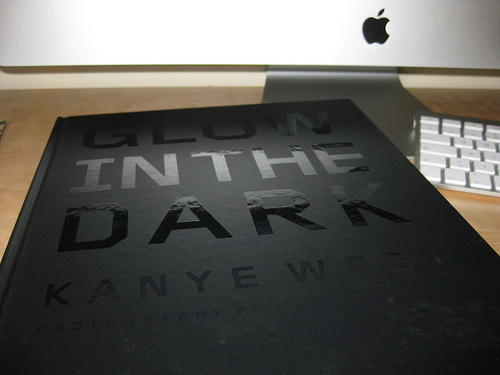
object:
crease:
[0, 116, 66, 300]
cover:
[0, 98, 500, 374]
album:
[0, 96, 500, 374]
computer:
[0, 0, 500, 157]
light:
[121, 153, 136, 173]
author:
[43, 247, 448, 308]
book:
[0, 97, 500, 374]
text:
[67, 139, 375, 195]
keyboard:
[413, 114, 500, 200]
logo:
[360, 7, 391, 46]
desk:
[0, 65, 500, 374]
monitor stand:
[259, 64, 439, 160]